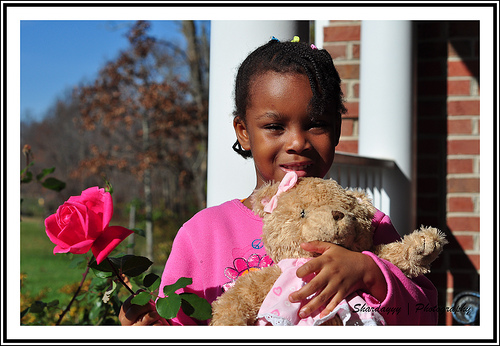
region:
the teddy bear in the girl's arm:
[207, 169, 448, 325]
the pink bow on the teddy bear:
[263, 170, 297, 213]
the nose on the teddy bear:
[330, 207, 345, 220]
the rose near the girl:
[42, 185, 132, 265]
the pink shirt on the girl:
[157, 197, 439, 332]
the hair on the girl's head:
[230, 37, 347, 159]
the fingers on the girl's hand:
[289, 240, 368, 320]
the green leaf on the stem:
[154, 294, 181, 317]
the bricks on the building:
[315, 21, 479, 324]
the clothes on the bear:
[254, 257, 386, 324]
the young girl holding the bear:
[115, 35, 449, 325]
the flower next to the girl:
[43, 184, 133, 264]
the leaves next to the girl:
[84, 254, 212, 326]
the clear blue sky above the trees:
[20, 21, 209, 123]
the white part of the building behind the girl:
[207, 20, 419, 237]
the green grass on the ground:
[20, 212, 165, 323]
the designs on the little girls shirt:
[221, 235, 271, 290]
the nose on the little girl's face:
[285, 122, 310, 152]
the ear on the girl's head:
[230, 115, 247, 150]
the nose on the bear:
[331, 209, 345, 221]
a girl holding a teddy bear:
[165, 21, 448, 338]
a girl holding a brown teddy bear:
[161, 35, 436, 325]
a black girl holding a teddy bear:
[209, 34, 451, 324]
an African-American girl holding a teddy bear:
[211, 39, 450, 322]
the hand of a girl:
[290, 236, 352, 317]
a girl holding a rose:
[45, 35, 350, 330]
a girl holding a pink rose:
[40, 35, 335, 337]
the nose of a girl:
[282, 137, 312, 153]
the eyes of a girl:
[258, 111, 328, 137]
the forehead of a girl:
[253, 70, 333, 107]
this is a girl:
[196, 50, 426, 317]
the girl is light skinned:
[316, 243, 358, 307]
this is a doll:
[273, 193, 357, 237]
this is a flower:
[55, 183, 100, 238]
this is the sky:
[38, 36, 67, 65]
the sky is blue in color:
[28, 31, 65, 70]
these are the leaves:
[140, 275, 193, 328]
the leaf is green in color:
[161, 289, 183, 324]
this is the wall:
[433, 48, 483, 151]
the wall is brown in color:
[428, 58, 493, 206]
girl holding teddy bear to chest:
[155, 35, 447, 320]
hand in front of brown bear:
[206, 172, 446, 318]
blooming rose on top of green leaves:
[35, 177, 207, 317]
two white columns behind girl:
[202, 20, 412, 220]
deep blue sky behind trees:
[20, 17, 202, 253]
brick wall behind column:
[320, 17, 475, 322]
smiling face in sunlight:
[230, 32, 342, 182]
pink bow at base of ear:
[245, 170, 300, 215]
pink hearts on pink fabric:
[252, 251, 382, 321]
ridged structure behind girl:
[323, 147, 404, 233]